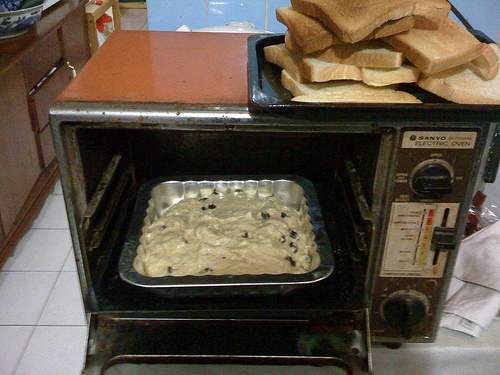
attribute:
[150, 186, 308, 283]
potatoes — wet, mashed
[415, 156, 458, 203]
knob — black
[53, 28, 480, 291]
microwave — dirty, orange, old, cooking, open, existing, present, here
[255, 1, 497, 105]
bread — piled, white, sliced, toasted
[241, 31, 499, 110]
pan — black, silver, square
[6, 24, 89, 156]
drawers — brown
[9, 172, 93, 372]
tile — white, blue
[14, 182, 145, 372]
floor — tiled